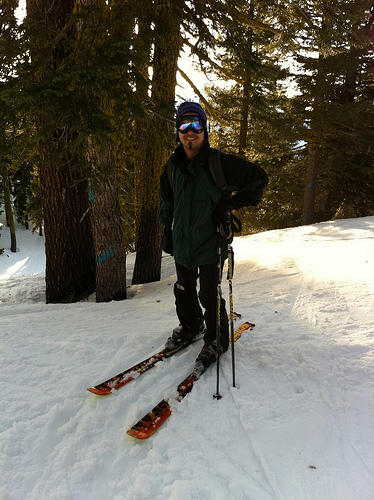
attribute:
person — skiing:
[88, 97, 274, 442]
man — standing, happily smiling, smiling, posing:
[91, 97, 276, 442]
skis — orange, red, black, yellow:
[89, 303, 257, 442]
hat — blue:
[176, 101, 210, 128]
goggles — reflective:
[178, 115, 205, 133]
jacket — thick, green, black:
[158, 145, 263, 268]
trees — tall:
[1, 4, 374, 306]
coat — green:
[152, 142, 270, 267]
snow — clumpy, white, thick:
[2, 213, 374, 491]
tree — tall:
[91, 134, 129, 299]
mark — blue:
[89, 183, 125, 275]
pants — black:
[171, 262, 237, 341]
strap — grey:
[206, 147, 227, 194]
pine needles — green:
[289, 1, 373, 178]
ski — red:
[127, 319, 259, 444]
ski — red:
[78, 310, 242, 402]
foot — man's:
[193, 341, 229, 371]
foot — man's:
[165, 322, 203, 353]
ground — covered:
[2, 216, 373, 493]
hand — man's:
[209, 201, 235, 228]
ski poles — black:
[215, 220, 239, 402]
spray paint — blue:
[85, 181, 122, 257]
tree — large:
[1, 1, 150, 314]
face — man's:
[174, 115, 207, 156]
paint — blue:
[91, 183, 122, 263]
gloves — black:
[154, 197, 238, 255]